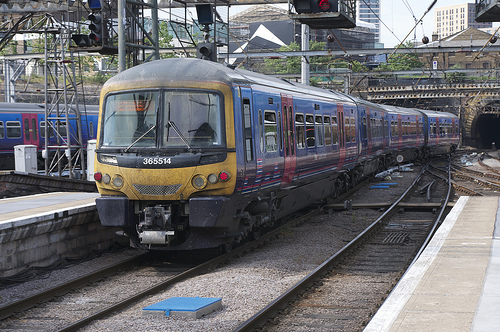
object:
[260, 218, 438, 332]
tracks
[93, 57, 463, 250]
train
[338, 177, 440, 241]
tracks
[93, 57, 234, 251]
engine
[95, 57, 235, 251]
front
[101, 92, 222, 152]
windows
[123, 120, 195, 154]
wipers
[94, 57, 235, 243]
engine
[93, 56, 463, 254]
cars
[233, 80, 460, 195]
sides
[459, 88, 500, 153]
tunnel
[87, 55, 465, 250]
train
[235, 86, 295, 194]
doors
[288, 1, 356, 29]
signal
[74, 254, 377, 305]
tracks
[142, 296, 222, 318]
object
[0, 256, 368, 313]
tracks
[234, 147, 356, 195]
lines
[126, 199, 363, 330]
track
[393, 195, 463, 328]
edge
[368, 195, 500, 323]
platform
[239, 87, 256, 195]
door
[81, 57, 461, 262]
train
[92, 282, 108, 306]
spot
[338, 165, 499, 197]
tracks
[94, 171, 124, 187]
light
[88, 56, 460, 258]
train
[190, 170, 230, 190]
light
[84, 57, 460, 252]
train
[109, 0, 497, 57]
building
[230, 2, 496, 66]
background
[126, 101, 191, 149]
wipers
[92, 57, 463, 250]
car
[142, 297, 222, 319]
box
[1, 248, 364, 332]
tracks